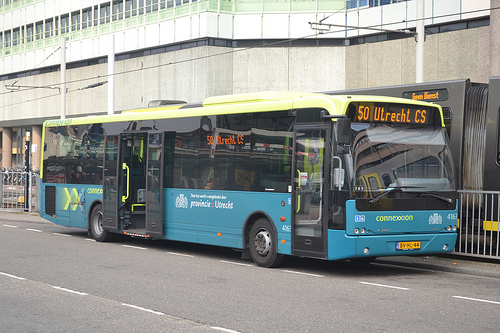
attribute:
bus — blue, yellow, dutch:
[35, 82, 469, 269]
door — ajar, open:
[119, 134, 154, 239]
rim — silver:
[251, 226, 274, 259]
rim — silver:
[90, 209, 106, 239]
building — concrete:
[0, 1, 499, 129]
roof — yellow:
[38, 92, 449, 134]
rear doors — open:
[99, 128, 173, 241]